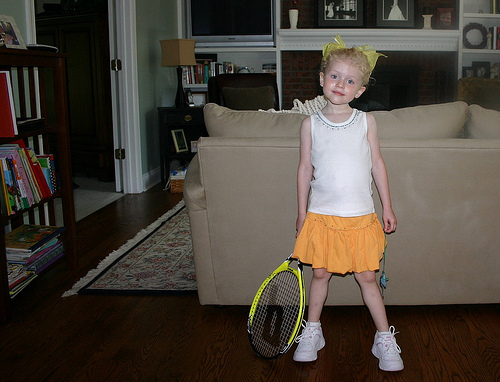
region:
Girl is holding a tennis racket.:
[240, 31, 426, 375]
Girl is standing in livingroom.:
[130, 10, 499, 376]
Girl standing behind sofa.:
[176, 87, 499, 328]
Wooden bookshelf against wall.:
[0, 13, 82, 320]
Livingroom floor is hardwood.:
[3, 147, 498, 379]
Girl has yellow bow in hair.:
[311, 33, 389, 83]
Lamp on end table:
[151, 27, 218, 190]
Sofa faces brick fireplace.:
[264, 25, 474, 184]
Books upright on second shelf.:
[0, 135, 77, 217]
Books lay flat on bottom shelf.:
[0, 217, 85, 302]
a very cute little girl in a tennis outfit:
[286, 42, 421, 375]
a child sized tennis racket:
[232, 244, 312, 364]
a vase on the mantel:
[283, 9, 299, 33]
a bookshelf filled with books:
[2, 43, 78, 294]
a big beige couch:
[180, 105, 496, 317]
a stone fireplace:
[271, 31, 471, 107]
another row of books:
[181, 50, 261, 90]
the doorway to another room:
[27, 2, 138, 214]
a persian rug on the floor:
[85, 205, 186, 291]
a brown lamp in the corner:
[160, 37, 198, 107]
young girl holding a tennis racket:
[236, 30, 416, 372]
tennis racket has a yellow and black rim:
[240, 241, 306, 358]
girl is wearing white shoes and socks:
[281, 305, 416, 370]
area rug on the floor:
[65, 180, 195, 310]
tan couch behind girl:
[182, 91, 497, 311]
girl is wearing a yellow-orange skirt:
[280, 205, 392, 278]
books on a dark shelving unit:
[0, 50, 71, 290]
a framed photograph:
[0, 5, 26, 50]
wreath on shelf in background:
[455, 10, 491, 53]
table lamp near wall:
[141, 28, 202, 118]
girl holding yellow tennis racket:
[245, 33, 405, 373]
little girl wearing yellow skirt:
[289, 210, 386, 275]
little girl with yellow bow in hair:
[319, 33, 386, 73]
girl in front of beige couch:
[181, 100, 498, 307]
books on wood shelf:
[4, 214, 64, 299]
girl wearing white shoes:
[291, 319, 403, 372]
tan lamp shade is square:
[156, 37, 198, 67]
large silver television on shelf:
[183, 0, 276, 45]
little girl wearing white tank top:
[306, 107, 375, 216]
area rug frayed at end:
[59, 192, 199, 298]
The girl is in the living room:
[103, 38, 450, 372]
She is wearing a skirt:
[292, 60, 474, 366]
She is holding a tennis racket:
[227, 189, 377, 367]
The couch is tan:
[153, 86, 468, 298]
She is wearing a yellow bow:
[306, 31, 397, 124]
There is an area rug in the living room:
[73, 128, 379, 349]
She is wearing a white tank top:
[272, 78, 417, 247]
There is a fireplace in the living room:
[253, 28, 494, 141]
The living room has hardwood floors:
[77, 304, 295, 377]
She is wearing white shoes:
[268, 299, 440, 364]